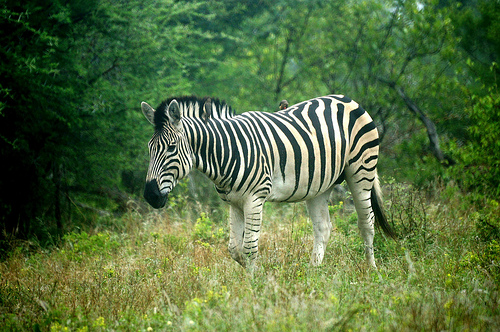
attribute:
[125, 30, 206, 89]
leaves — green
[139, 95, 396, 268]
zebra — standing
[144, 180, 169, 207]
nose — black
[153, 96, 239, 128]
hair — black and white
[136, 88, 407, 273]
zebra — black 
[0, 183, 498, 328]
grass — tall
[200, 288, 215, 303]
flowers — yellow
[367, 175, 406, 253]
tail — black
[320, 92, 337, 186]
stripe — black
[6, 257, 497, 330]
grass — brown and green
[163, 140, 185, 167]
eyes — dark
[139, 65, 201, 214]
head — striped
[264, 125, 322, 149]
pattern — White 